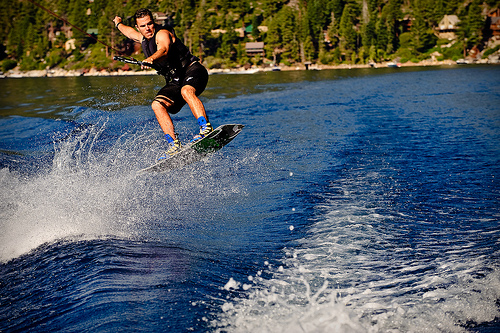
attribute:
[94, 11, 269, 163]
man — white, boarding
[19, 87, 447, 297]
water — blue, white, calm, deep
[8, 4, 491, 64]
trees — green, tall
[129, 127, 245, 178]
board — black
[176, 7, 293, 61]
houses — white